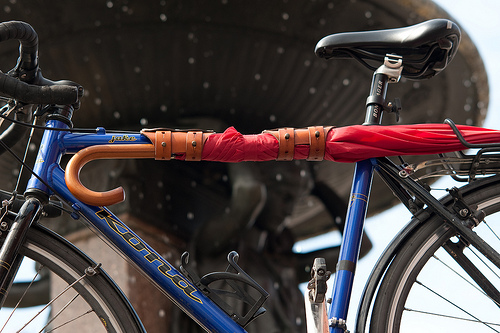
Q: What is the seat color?
A: Black.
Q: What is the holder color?
A: Black.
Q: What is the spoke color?
A: Silver.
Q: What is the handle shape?
A: Curved.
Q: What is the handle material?
A: Wood.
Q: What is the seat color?
A: Black.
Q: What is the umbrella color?
A: Red.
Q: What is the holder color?
A: Black.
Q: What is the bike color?
A: Blue.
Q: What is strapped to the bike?
A: An umbrella.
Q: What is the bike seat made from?
A: Plastic.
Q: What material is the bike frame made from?
A: Aluminum.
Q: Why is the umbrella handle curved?
A: For ease of holding.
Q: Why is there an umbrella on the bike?
A: In case it rains.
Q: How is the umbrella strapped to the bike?
A: Leather straps.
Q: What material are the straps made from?
A: Leather.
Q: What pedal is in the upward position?
A: The left pedal.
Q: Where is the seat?
A: On the bike.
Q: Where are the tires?
A: On the bike.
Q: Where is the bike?
A: In front of a statue.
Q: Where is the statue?
A: Behind the bike.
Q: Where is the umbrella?
A: On the bike.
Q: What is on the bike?
A: An umbrella.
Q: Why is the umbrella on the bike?
A: Rain.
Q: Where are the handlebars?
A: On the front of the bike.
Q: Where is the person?
A: Part of the statue.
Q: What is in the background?
A: Statue of a woman.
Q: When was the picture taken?
A: Daytime.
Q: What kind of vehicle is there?
A: A bicycle.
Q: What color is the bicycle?
A: Blue.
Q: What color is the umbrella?
A: Red.